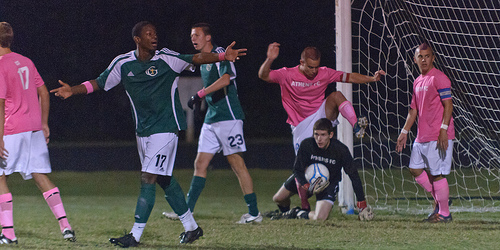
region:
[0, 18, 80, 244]
soccer player wearing a pink shirt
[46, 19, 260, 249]
two soccer players in green and white uniforms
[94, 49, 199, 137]
green and white soccer jersey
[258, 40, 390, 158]
soccer player in pink with his foot raised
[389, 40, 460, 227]
soccer player wearing white bands on his wrist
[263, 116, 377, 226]
soccer player down on a grassy field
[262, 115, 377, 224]
soccer player holding onto a soccer ball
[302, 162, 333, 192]
blue and white soccer ball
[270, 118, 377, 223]
soccer player wearing a black long sleeve shirt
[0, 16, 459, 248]
soccer players on a grassy field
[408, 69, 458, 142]
a pink shirt on a man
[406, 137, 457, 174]
white shorts on a man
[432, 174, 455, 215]
a pink sock on a man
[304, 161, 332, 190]
a soccer ball in a man's hand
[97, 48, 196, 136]
a green and white shirt on a man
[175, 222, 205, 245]
a black shoe on a man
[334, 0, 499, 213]
a soccer net behind a man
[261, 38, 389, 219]
a man lifting his leg over a goalie's head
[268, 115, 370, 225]
a goalie kneeling on the ground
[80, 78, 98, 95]
a pink armband on a man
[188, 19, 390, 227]
Men playing soccer on field.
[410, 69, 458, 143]
Man wearing pink t-shirt.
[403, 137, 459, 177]
Man wearing white shorts.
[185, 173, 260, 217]
Man wearing green socks.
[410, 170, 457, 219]
Man wearing pink socks.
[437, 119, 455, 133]
Man wearing white band around wrist.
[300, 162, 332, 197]
Man holding white and blue soccer ball.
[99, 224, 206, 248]
Man wearing black soccer shoes.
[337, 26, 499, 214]
Goalie net in background.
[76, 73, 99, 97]
Man wearing pink band around wrist.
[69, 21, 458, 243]
men that are playing soccer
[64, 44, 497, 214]
men wearing soccer uniforms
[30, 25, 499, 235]
men walkin gon the field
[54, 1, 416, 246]
men walking on grass field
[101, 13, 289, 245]
men wearing green soccer uniform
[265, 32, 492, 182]
men wearing pink uniform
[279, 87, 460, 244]
man holding soccer ball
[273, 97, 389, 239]
a man holding a ball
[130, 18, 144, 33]
man has black hair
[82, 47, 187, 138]
green and white shirt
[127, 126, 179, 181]
green and white shorts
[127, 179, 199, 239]
green and white socks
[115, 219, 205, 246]
man has green shoes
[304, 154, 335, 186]
blue and white ball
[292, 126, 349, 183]
man has black shirt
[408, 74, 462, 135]
pink and white shirt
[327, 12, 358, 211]
white crossbar on goal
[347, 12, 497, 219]
white net in goal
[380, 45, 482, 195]
a man on the field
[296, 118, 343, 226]
a man on the field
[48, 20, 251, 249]
man is wearing a pink arm band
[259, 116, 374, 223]
man is wearing a black long sleeve shirt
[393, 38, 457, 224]
man is wearing a pink shirt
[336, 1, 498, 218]
white net attached to goal post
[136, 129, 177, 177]
number 17 on white shorts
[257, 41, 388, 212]
man is lifting his leg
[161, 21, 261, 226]
man is wearing a black glove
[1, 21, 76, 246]
man is wearing pink socks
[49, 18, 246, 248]
man is wearing a green and white shirt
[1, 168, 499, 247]
grass is green and short